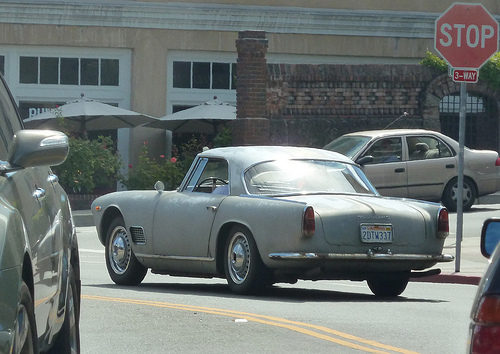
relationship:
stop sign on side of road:
[431, 1, 499, 70] [76, 203, 498, 353]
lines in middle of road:
[79, 292, 417, 354] [76, 203, 498, 353]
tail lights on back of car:
[299, 204, 449, 239] [90, 143, 454, 296]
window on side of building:
[19, 54, 38, 84] [1, 0, 499, 192]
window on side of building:
[40, 57, 60, 84] [1, 0, 499, 192]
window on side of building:
[60, 56, 79, 85] [1, 0, 499, 192]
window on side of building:
[79, 57, 99, 87] [1, 0, 499, 192]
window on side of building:
[100, 57, 118, 87] [1, 0, 499, 192]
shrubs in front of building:
[48, 107, 230, 193] [1, 0, 499, 192]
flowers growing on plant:
[126, 154, 179, 170] [118, 137, 183, 191]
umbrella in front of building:
[144, 96, 235, 138] [1, 0, 499, 192]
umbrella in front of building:
[19, 93, 155, 141] [1, 0, 499, 192]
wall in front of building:
[235, 28, 498, 154] [1, 0, 499, 192]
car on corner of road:
[90, 143, 454, 296] [76, 203, 498, 353]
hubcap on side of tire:
[229, 235, 251, 278] [224, 222, 267, 294]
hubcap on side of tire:
[111, 227, 131, 269] [103, 215, 147, 285]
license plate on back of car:
[358, 222, 393, 244] [90, 143, 454, 296]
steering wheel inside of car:
[195, 174, 228, 193] [90, 143, 454, 296]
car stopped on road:
[90, 143, 454, 296] [76, 203, 498, 353]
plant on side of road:
[118, 137, 183, 191] [76, 203, 498, 353]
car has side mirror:
[90, 143, 454, 296] [154, 178, 167, 193]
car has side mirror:
[0, 73, 83, 353] [2, 128, 70, 176]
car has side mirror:
[322, 127, 499, 211] [355, 154, 374, 167]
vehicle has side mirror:
[467, 217, 499, 353] [477, 216, 499, 259]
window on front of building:
[101, 59, 118, 86] [1, 0, 499, 192]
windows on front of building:
[172, 59, 242, 90] [1, 0, 499, 192]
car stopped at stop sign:
[90, 143, 454, 296] [431, 1, 499, 70]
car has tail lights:
[90, 143, 454, 296] [299, 204, 449, 239]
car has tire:
[90, 143, 454, 296] [105, 217, 149, 285]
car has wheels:
[0, 73, 83, 353] [19, 264, 84, 353]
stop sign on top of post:
[431, 1, 499, 70] [453, 80, 465, 274]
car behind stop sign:
[322, 127, 499, 211] [431, 1, 499, 70]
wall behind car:
[235, 28, 498, 154] [322, 127, 499, 211]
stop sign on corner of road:
[431, 1, 499, 70] [76, 203, 498, 353]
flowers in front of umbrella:
[126, 154, 179, 170] [144, 96, 235, 138]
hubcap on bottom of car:
[227, 232, 251, 284] [90, 143, 454, 296]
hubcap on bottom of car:
[111, 227, 131, 269] [90, 143, 454, 296]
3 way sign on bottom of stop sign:
[449, 67, 478, 84] [431, 1, 499, 70]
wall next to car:
[235, 28, 498, 154] [322, 127, 499, 211]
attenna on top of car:
[378, 110, 408, 132] [322, 127, 499, 211]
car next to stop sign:
[90, 143, 454, 296] [431, 1, 499, 70]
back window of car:
[240, 157, 379, 195] [90, 143, 454, 296]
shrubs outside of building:
[48, 107, 230, 193] [1, 0, 499, 192]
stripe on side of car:
[373, 180, 443, 190] [322, 127, 499, 211]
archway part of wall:
[419, 71, 498, 136] [235, 28, 498, 154]